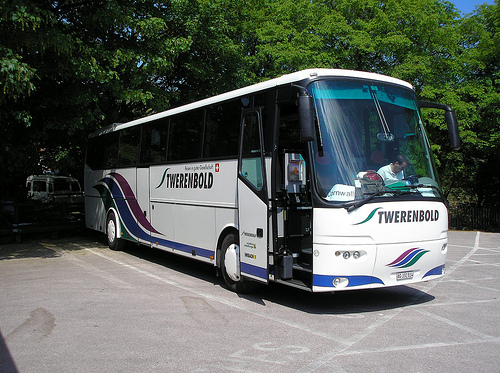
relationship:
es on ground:
[227, 335, 310, 366] [1, 228, 484, 371]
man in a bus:
[377, 153, 411, 186] [77, 64, 464, 300]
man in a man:
[377, 153, 411, 186] [377, 153, 411, 186]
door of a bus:
[233, 101, 275, 291] [77, 64, 464, 300]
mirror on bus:
[416, 97, 465, 155] [77, 64, 464, 300]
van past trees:
[20, 170, 84, 205] [3, 2, 483, 192]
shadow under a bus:
[121, 247, 437, 317] [77, 64, 464, 300]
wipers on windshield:
[367, 86, 394, 137] [306, 78, 446, 203]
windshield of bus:
[306, 78, 446, 203] [77, 64, 464, 300]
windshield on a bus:
[306, 78, 446, 203] [77, 64, 464, 300]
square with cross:
[212, 160, 222, 172] [214, 163, 219, 169]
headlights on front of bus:
[331, 240, 450, 258] [77, 64, 464, 300]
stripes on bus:
[91, 169, 162, 244] [77, 64, 464, 300]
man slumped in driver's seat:
[377, 153, 411, 186] [362, 150, 388, 172]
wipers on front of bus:
[367, 86, 394, 137] [77, 64, 464, 300]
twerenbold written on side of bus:
[163, 170, 216, 189] [77, 64, 464, 300]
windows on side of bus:
[84, 90, 283, 173] [77, 64, 464, 300]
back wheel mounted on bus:
[101, 209, 124, 250] [77, 64, 464, 300]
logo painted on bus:
[350, 205, 440, 225] [77, 64, 464, 300]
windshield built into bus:
[306, 78, 446, 203] [77, 64, 464, 300]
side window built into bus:
[95, 129, 120, 169] [77, 64, 464, 300]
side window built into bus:
[141, 116, 169, 166] [77, 64, 464, 300]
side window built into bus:
[166, 106, 206, 162] [77, 64, 464, 300]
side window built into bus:
[200, 94, 244, 158] [77, 64, 464, 300]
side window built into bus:
[251, 90, 275, 153] [77, 64, 464, 300]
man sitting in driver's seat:
[377, 153, 411, 186] [362, 150, 388, 172]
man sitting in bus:
[377, 153, 411, 186] [77, 64, 464, 300]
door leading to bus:
[233, 101, 275, 291] [77, 64, 464, 300]